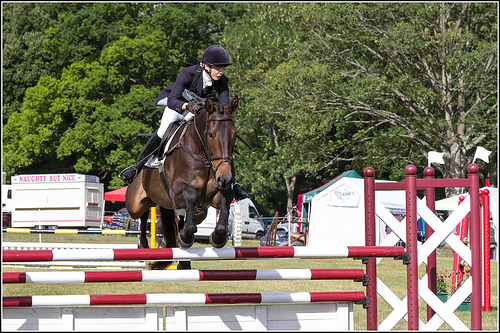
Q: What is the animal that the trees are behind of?
A: The animal is a horse.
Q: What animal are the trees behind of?
A: The trees are behind the horse.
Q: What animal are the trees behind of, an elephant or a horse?
A: The trees are behind a horse.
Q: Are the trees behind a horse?
A: Yes, the trees are behind a horse.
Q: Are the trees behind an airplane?
A: No, the trees are behind a horse.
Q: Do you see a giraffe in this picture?
A: No, there are no giraffes.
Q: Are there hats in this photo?
A: Yes, there is a hat.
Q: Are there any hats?
A: Yes, there is a hat.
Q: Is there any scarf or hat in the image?
A: Yes, there is a hat.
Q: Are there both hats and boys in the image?
A: No, there is a hat but no boys.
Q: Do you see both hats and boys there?
A: No, there is a hat but no boys.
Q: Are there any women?
A: Yes, there is a woman.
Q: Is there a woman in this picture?
A: Yes, there is a woman.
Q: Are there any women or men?
A: Yes, there is a woman.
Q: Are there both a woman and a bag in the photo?
A: No, there is a woman but no bags.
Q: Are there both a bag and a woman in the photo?
A: No, there is a woman but no bags.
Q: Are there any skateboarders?
A: No, there are no skateboarders.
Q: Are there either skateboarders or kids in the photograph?
A: No, there are no skateboarders or kids.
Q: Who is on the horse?
A: The woman is on the horse.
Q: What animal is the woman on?
A: The woman is on the horse.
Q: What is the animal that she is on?
A: The animal is a horse.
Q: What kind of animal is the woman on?
A: The woman is on the horse.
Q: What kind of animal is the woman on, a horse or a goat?
A: The woman is on a horse.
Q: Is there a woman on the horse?
A: Yes, there is a woman on the horse.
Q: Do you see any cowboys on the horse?
A: No, there is a woman on the horse.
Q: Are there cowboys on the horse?
A: No, there is a woman on the horse.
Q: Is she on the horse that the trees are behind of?
A: Yes, the woman is on the horse.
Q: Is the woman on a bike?
A: No, the woman is on the horse.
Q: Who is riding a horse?
A: The woman is riding a horse.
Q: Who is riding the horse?
A: The woman is riding a horse.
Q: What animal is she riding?
A: The woman is riding a horse.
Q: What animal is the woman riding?
A: The woman is riding a horse.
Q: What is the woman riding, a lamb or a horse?
A: The woman is riding a horse.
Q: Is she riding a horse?
A: Yes, the woman is riding a horse.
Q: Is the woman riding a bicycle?
A: No, the woman is riding a horse.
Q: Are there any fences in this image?
A: Yes, there is a fence.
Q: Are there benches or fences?
A: Yes, there is a fence.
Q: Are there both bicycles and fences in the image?
A: No, there is a fence but no bicycles.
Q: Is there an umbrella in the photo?
A: No, there are no umbrellas.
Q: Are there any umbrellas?
A: No, there are no umbrellas.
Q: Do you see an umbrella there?
A: No, there are no umbrellas.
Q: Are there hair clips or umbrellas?
A: No, there are no umbrellas or hair clips.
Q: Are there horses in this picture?
A: Yes, there is a horse.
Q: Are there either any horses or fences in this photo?
A: Yes, there is a horse.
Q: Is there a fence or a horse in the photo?
A: Yes, there is a horse.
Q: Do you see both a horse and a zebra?
A: No, there is a horse but no zebras.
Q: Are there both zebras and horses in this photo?
A: No, there is a horse but no zebras.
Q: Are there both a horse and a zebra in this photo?
A: No, there is a horse but no zebras.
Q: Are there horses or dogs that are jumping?
A: Yes, the horse is jumping.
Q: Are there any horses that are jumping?
A: Yes, there is a horse that is jumping.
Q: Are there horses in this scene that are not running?
A: Yes, there is a horse that is jumping.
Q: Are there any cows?
A: No, there are no cows.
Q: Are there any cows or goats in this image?
A: No, there are no cows or goats.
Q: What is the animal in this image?
A: The animal is a horse.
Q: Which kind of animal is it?
A: The animal is a horse.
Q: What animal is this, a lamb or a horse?
A: That is a horse.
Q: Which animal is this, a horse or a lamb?
A: That is a horse.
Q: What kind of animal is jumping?
A: The animal is a horse.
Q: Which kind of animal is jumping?
A: The animal is a horse.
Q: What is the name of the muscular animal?
A: The animal is a horse.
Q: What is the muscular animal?
A: The animal is a horse.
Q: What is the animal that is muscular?
A: The animal is a horse.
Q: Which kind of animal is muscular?
A: The animal is a horse.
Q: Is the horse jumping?
A: Yes, the horse is jumping.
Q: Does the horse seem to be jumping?
A: Yes, the horse is jumping.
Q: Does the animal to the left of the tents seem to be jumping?
A: Yes, the horse is jumping.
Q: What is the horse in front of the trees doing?
A: The horse is jumping.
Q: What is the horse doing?
A: The horse is jumping.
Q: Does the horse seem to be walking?
A: No, the horse is jumping.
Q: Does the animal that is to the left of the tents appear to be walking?
A: No, the horse is jumping.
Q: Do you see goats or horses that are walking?
A: No, there is a horse but it is jumping.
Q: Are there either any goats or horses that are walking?
A: No, there is a horse but it is jumping.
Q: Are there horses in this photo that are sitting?
A: No, there is a horse but it is jumping.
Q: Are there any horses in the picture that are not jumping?
A: No, there is a horse but it is jumping.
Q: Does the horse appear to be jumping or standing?
A: The horse is jumping.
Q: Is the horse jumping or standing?
A: The horse is jumping.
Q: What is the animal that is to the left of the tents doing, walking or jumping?
A: The horse is jumping.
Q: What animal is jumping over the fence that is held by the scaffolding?
A: The horse is jumping over the fence.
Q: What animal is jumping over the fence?
A: The horse is jumping over the fence.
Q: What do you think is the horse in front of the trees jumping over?
A: The horse is jumping over the fence.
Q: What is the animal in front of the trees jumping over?
A: The horse is jumping over the fence.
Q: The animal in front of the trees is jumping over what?
A: The horse is jumping over the fence.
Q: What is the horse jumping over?
A: The horse is jumping over the fence.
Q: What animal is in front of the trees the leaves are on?
A: The horse is in front of the trees.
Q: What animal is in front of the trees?
A: The animal is a horse.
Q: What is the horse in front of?
A: The horse is in front of the trees.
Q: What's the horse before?
A: The horse is in front of the trees.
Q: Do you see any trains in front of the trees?
A: No, there is a horse in front of the trees.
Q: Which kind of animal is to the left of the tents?
A: The animal is a horse.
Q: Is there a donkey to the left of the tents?
A: No, there is a horse to the left of the tents.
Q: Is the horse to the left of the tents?
A: Yes, the horse is to the left of the tents.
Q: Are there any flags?
A: Yes, there is a flag.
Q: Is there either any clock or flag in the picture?
A: Yes, there is a flag.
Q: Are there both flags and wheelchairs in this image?
A: No, there is a flag but no wheelchairs.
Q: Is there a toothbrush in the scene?
A: No, there are no toothbrushes.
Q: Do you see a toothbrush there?
A: No, there are no toothbrushes.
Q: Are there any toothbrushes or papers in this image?
A: No, there are no toothbrushes or papers.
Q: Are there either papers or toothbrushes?
A: No, there are no toothbrushes or papers.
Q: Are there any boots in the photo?
A: Yes, there are boots.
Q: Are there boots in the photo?
A: Yes, there are boots.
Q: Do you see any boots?
A: Yes, there are boots.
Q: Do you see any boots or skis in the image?
A: Yes, there are boots.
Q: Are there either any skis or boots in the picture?
A: Yes, there are boots.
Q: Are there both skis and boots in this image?
A: No, there are boots but no skis.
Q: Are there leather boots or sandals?
A: Yes, there are leather boots.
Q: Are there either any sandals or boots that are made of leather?
A: Yes, the boots are made of leather.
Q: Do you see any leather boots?
A: Yes, there are boots that are made of leather.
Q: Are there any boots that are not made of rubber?
A: Yes, there are boots that are made of leather.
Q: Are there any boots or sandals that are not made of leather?
A: No, there are boots but they are made of leather.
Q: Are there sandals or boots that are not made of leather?
A: No, there are boots but they are made of leather.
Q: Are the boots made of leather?
A: Yes, the boots are made of leather.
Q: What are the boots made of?
A: The boots are made of leather.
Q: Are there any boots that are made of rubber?
A: No, there are boots but they are made of leather.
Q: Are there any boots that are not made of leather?
A: No, there are boots but they are made of leather.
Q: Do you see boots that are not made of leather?
A: No, there are boots but they are made of leather.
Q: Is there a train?
A: No, there are no trains.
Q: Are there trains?
A: No, there are no trains.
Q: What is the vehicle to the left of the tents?
A: The vehicle is a van.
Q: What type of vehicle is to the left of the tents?
A: The vehicle is a van.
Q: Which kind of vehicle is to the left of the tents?
A: The vehicle is a van.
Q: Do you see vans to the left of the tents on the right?
A: Yes, there is a van to the left of the tents.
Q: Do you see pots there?
A: No, there are no pots.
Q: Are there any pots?
A: No, there are no pots.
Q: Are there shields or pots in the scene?
A: No, there are no pots or shields.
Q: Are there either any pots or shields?
A: No, there are no pots or shields.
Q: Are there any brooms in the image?
A: No, there are no brooms.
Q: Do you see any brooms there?
A: No, there are no brooms.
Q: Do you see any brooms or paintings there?
A: No, there are no brooms or paintings.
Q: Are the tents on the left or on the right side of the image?
A: The tents are on the right of the image.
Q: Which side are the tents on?
A: The tents are on the right of the image.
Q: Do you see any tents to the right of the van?
A: Yes, there are tents to the right of the van.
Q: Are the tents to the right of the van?
A: Yes, the tents are to the right of the van.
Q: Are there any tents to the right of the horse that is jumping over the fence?
A: Yes, there are tents to the right of the horse.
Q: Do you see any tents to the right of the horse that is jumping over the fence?
A: Yes, there are tents to the right of the horse.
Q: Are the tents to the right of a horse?
A: Yes, the tents are to the right of a horse.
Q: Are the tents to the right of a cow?
A: No, the tents are to the right of a horse.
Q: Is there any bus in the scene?
A: No, there are no buses.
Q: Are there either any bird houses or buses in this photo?
A: No, there are no buses or bird houses.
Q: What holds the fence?
A: The scaffolding holds the fence.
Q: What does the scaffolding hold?
A: The scaffolding holds the fence.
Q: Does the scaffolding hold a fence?
A: Yes, the scaffolding holds a fence.